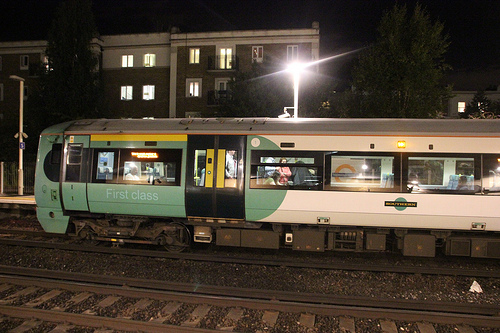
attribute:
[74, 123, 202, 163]
strip — yellow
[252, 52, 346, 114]
light — bright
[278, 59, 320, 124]
light — bright, white,  narrow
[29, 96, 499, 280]
train — long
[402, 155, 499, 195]
window — long, clear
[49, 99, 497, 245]
train — long, tan, green, yellow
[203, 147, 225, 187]
strip — yellow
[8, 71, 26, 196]
streetlight off — turned off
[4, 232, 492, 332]
track — empty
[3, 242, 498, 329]
train tracks — metal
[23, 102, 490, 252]
train — compartment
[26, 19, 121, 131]
tree — leafy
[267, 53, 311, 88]
light — bright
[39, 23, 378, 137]
building — big, brown,  Square,  Short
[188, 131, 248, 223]
doors — Yellow,  skinny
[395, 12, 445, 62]
leaves — many, green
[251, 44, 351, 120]
light — bright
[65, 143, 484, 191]
windows — line